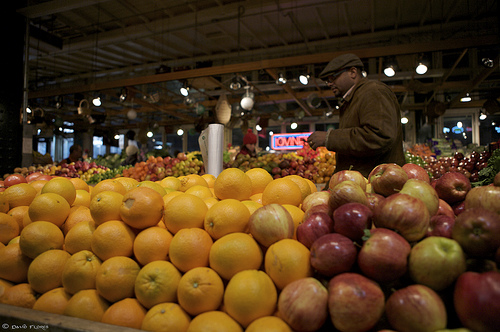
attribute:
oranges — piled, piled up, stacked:
[0, 169, 313, 331]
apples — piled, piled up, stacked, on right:
[282, 161, 500, 330]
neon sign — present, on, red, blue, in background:
[270, 131, 313, 151]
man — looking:
[309, 52, 406, 177]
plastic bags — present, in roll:
[198, 123, 225, 176]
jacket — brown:
[329, 79, 402, 171]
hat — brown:
[318, 53, 361, 78]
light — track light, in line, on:
[92, 98, 101, 106]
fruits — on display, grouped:
[1, 165, 499, 331]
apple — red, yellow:
[386, 285, 445, 331]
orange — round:
[210, 233, 264, 280]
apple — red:
[334, 202, 372, 240]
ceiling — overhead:
[23, 1, 499, 104]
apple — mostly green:
[410, 238, 465, 287]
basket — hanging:
[74, 99, 91, 116]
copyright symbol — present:
[0, 319, 8, 331]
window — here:
[63, 137, 71, 158]